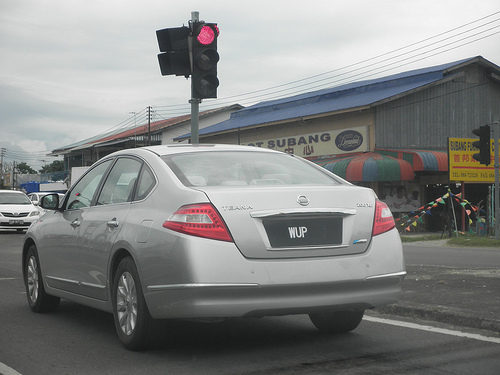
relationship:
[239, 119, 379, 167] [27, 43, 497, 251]
writing on side of building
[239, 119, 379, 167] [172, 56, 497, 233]
writing on building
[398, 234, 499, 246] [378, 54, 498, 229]
grass in front of front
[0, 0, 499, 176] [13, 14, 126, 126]
sky has clouds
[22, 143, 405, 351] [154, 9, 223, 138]
car stopped at a light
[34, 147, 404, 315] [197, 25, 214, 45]
car stopped at a red light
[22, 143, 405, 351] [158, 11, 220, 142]
car stopped at a light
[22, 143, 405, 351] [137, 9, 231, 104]
car stopped at a light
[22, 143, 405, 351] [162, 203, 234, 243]
car stopped at a light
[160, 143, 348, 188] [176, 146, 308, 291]
window on car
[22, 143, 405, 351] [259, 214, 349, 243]
car without numberplates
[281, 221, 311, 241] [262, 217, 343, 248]
letters on numberplates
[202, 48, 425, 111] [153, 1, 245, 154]
wires on poles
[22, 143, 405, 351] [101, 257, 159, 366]
car has tire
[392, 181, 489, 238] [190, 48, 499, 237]
flags on building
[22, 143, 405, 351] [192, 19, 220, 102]
car at a red light